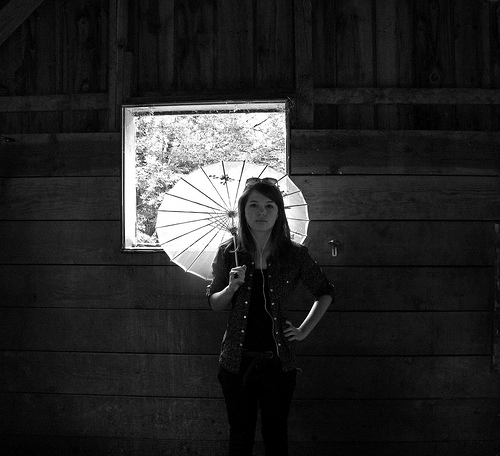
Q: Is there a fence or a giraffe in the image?
A: No, there are no fences or giraffes.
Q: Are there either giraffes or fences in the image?
A: No, there are no fences or giraffes.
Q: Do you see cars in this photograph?
A: No, there are no cars.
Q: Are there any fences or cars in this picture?
A: No, there are no cars or fences.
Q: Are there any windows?
A: Yes, there is a window.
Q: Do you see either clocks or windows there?
A: Yes, there is a window.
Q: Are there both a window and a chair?
A: No, there is a window but no chairs.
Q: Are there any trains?
A: No, there are no trains.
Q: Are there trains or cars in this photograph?
A: No, there are no trains or cars.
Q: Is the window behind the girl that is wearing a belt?
A: Yes, the window is behind the girl.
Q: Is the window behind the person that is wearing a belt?
A: Yes, the window is behind the girl.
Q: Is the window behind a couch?
A: No, the window is behind the girl.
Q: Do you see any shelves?
A: No, there are no shelves.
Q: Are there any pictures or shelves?
A: No, there are no shelves or pictures.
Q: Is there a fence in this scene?
A: No, there are no fences.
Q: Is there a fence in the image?
A: No, there are no fences.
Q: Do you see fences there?
A: No, there are no fences.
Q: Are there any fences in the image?
A: No, there are no fences.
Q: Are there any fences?
A: No, there are no fences.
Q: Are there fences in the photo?
A: No, there are no fences.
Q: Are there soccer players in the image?
A: No, there are no soccer players.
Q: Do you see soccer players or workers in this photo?
A: No, there are no soccer players or workers.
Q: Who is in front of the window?
A: The girl is in front of the window.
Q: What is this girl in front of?
A: The girl is in front of the window.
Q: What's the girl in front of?
A: The girl is in front of the window.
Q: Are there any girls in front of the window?
A: Yes, there is a girl in front of the window.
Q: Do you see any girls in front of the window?
A: Yes, there is a girl in front of the window.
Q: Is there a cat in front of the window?
A: No, there is a girl in front of the window.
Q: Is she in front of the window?
A: Yes, the girl is in front of the window.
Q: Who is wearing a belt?
A: The girl is wearing a belt.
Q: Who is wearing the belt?
A: The girl is wearing a belt.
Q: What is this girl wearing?
A: The girl is wearing a belt.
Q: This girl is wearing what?
A: The girl is wearing a belt.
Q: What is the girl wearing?
A: The girl is wearing a belt.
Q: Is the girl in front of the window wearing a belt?
A: Yes, the girl is wearing a belt.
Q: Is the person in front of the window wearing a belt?
A: Yes, the girl is wearing a belt.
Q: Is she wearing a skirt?
A: No, the girl is wearing a belt.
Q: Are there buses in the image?
A: No, there are no buses.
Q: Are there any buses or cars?
A: No, there are no buses or cars.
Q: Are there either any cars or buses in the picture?
A: No, there are no buses or cars.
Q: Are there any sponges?
A: No, there are no sponges.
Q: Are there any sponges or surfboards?
A: No, there are no sponges or surfboards.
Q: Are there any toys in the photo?
A: No, there are no toys.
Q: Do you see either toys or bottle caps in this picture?
A: No, there are no toys or bottle caps.